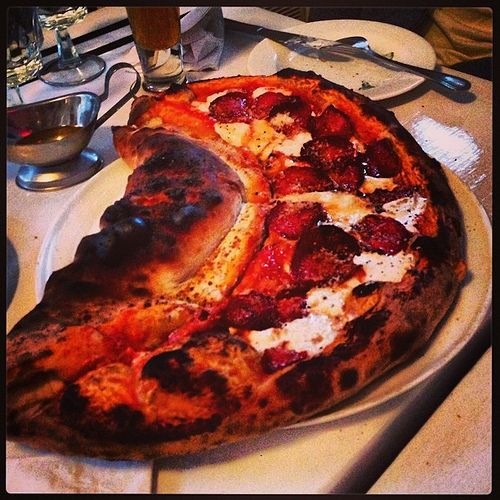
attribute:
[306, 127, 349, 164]
pepperoni — topping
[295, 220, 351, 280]
pepperoni — topping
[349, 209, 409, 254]
pepperoni — topping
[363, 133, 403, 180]
pepperoni — topping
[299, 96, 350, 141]
pepperoni — topping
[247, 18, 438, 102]
plate — white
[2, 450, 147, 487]
napkins — white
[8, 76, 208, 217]
dish — silver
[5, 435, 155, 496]
napkin — white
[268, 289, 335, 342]
cheese — melted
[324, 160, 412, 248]
cheese — melted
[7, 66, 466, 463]
pizza — burnt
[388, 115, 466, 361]
crust — burnt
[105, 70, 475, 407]
pizza — burnt, disfigured